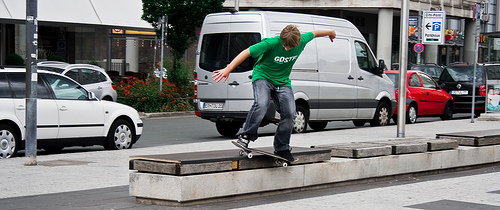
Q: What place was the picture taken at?
A: It was taken at the sidewalk.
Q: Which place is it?
A: It is a sidewalk.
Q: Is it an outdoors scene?
A: Yes, it is outdoors.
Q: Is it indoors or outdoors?
A: It is outdoors.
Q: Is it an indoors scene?
A: No, it is outdoors.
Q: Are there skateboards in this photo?
A: Yes, there is a skateboard.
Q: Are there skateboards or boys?
A: Yes, there is a skateboard.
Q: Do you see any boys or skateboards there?
A: Yes, there is a skateboard.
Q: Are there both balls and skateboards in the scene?
A: No, there is a skateboard but no balls.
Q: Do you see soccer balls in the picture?
A: No, there are no soccer balls.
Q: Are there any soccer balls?
A: No, there are no soccer balls.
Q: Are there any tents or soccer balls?
A: No, there are no soccer balls or tents.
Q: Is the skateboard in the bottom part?
A: Yes, the skateboard is in the bottom of the image.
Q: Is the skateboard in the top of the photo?
A: No, the skateboard is in the bottom of the image.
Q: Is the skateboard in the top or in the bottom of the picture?
A: The skateboard is in the bottom of the image.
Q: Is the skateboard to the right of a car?
A: Yes, the skateboard is to the right of a car.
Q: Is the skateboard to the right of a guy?
A: No, the skateboard is to the right of a car.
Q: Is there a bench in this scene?
A: Yes, there is a bench.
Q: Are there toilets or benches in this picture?
A: Yes, there is a bench.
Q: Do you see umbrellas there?
A: No, there are no umbrellas.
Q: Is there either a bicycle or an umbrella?
A: No, there are no umbrellas or bicycles.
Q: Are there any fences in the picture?
A: No, there are no fences.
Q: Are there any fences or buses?
A: No, there are no fences or buses.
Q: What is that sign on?
A: The sign is on the pole.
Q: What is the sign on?
A: The sign is on the pole.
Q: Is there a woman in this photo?
A: No, there are no women.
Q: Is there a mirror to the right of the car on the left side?
A: No, there is a boy to the right of the car.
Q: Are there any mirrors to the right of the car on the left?
A: No, there is a boy to the right of the car.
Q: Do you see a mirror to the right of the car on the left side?
A: No, there is a boy to the right of the car.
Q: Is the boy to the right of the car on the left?
A: Yes, the boy is to the right of the car.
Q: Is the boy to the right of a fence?
A: No, the boy is to the right of the car.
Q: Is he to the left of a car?
A: No, the boy is to the right of a car.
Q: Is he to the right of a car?
A: No, the boy is to the left of a car.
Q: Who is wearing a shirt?
A: The boy is wearing a shirt.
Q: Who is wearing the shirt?
A: The boy is wearing a shirt.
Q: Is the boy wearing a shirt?
A: Yes, the boy is wearing a shirt.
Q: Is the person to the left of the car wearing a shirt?
A: Yes, the boy is wearing a shirt.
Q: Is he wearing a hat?
A: No, the boy is wearing a shirt.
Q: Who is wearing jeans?
A: The boy is wearing jeans.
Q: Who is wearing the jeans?
A: The boy is wearing jeans.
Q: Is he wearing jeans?
A: Yes, the boy is wearing jeans.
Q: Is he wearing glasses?
A: No, the boy is wearing jeans.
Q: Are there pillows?
A: No, there are no pillows.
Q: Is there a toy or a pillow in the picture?
A: No, there are no pillows or toys.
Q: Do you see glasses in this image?
A: No, there are no glasses.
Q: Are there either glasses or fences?
A: No, there are no glasses or fences.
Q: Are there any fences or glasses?
A: No, there are no glasses or fences.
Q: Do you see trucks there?
A: No, there are no trucks.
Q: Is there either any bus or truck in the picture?
A: No, there are no trucks or buses.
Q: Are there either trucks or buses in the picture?
A: No, there are no trucks or buses.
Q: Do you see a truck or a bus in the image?
A: No, there are no trucks or buses.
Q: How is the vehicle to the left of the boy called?
A: The vehicle is a car.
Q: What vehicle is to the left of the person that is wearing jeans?
A: The vehicle is a car.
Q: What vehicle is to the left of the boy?
A: The vehicle is a car.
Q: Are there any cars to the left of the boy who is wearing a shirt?
A: Yes, there is a car to the left of the boy.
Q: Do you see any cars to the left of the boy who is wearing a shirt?
A: Yes, there is a car to the left of the boy.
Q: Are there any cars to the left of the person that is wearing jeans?
A: Yes, there is a car to the left of the boy.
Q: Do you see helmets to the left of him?
A: No, there is a car to the left of the boy.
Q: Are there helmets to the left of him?
A: No, there is a car to the left of the boy.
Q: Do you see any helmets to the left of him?
A: No, there is a car to the left of the boy.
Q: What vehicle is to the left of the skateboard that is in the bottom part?
A: The vehicle is a car.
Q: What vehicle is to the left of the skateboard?
A: The vehicle is a car.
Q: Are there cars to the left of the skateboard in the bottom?
A: Yes, there is a car to the left of the skateboard.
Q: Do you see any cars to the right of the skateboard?
A: No, the car is to the left of the skateboard.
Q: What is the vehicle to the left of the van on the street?
A: The vehicle is a car.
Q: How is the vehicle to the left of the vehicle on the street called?
A: The vehicle is a car.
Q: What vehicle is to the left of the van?
A: The vehicle is a car.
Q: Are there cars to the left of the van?
A: Yes, there is a car to the left of the van.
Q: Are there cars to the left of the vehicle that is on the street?
A: Yes, there is a car to the left of the van.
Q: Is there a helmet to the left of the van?
A: No, there is a car to the left of the van.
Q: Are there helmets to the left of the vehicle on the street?
A: No, there is a car to the left of the van.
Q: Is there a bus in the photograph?
A: No, there are no buses.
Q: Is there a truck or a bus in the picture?
A: No, there are no buses or trucks.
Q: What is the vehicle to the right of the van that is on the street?
A: The vehicle is a car.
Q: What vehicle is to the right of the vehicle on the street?
A: The vehicle is a car.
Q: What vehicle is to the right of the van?
A: The vehicle is a car.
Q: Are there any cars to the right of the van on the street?
A: Yes, there is a car to the right of the van.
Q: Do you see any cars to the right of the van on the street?
A: Yes, there is a car to the right of the van.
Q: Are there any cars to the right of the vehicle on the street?
A: Yes, there is a car to the right of the van.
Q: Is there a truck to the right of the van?
A: No, there is a car to the right of the van.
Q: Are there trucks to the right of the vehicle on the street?
A: No, there is a car to the right of the van.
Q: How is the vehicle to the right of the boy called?
A: The vehicle is a car.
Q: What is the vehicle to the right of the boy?
A: The vehicle is a car.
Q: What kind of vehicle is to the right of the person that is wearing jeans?
A: The vehicle is a car.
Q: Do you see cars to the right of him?
A: Yes, there is a car to the right of the boy.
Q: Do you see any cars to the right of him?
A: Yes, there is a car to the right of the boy.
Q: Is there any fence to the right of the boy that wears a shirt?
A: No, there is a car to the right of the boy.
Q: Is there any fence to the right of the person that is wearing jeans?
A: No, there is a car to the right of the boy.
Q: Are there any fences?
A: No, there are no fences.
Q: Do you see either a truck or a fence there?
A: No, there are no fences or trucks.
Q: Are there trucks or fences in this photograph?
A: No, there are no fences or trucks.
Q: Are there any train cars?
A: No, there are no train cars.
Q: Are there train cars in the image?
A: No, there are no train cars.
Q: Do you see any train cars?
A: No, there are no train cars.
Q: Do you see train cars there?
A: No, there are no train cars.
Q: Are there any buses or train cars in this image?
A: No, there are no train cars or buses.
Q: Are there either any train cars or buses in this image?
A: No, there are no train cars or buses.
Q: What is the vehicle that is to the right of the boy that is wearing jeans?
A: The vehicle is a car.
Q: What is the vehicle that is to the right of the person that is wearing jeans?
A: The vehicle is a car.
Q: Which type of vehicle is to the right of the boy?
A: The vehicle is a car.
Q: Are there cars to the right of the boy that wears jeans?
A: Yes, there is a car to the right of the boy.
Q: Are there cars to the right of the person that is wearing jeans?
A: Yes, there is a car to the right of the boy.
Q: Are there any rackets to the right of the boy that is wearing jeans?
A: No, there is a car to the right of the boy.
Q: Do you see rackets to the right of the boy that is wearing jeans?
A: No, there is a car to the right of the boy.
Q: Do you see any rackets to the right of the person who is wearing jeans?
A: No, there is a car to the right of the boy.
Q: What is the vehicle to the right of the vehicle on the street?
A: The vehicle is a car.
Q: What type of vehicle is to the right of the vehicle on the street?
A: The vehicle is a car.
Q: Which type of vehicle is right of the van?
A: The vehicle is a car.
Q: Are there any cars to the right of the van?
A: Yes, there is a car to the right of the van.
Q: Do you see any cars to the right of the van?
A: Yes, there is a car to the right of the van.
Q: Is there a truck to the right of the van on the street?
A: No, there is a car to the right of the van.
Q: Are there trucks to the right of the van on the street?
A: No, there is a car to the right of the van.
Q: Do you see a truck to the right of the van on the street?
A: No, there is a car to the right of the van.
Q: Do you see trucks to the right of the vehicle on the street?
A: No, there is a car to the right of the van.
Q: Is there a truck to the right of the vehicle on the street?
A: No, there is a car to the right of the van.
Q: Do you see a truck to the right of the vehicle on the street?
A: No, there is a car to the right of the van.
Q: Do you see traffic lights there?
A: No, there are no traffic lights.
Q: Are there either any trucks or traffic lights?
A: No, there are no traffic lights or trucks.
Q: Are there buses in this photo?
A: No, there are no buses.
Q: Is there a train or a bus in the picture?
A: No, there are no buses or trains.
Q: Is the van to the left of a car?
A: Yes, the van is to the left of a car.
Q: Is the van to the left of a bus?
A: No, the van is to the left of a car.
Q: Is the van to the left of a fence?
A: No, the van is to the left of a car.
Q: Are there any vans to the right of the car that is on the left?
A: Yes, there is a van to the right of the car.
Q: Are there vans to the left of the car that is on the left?
A: No, the van is to the right of the car.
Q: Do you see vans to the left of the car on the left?
A: No, the van is to the right of the car.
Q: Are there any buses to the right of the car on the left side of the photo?
A: No, there is a van to the right of the car.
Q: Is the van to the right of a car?
A: Yes, the van is to the right of a car.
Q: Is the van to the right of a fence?
A: No, the van is to the right of a car.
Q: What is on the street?
A: The van is on the street.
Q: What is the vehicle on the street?
A: The vehicle is a van.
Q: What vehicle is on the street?
A: The vehicle is a van.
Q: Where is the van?
A: The van is on the street.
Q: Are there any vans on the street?
A: Yes, there is a van on the street.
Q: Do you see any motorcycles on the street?
A: No, there is a van on the street.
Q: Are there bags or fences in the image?
A: No, there are no fences or bags.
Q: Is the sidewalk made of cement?
A: Yes, the sidewalk is made of cement.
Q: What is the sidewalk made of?
A: The sidewalk is made of concrete.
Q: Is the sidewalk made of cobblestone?
A: No, the sidewalk is made of concrete.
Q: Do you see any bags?
A: No, there are no bags.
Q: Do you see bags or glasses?
A: No, there are no bags or glasses.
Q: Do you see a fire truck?
A: No, there are no fire trucks.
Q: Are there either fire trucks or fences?
A: No, there are no fire trucks or fences.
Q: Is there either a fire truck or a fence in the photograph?
A: No, there are no fire trucks or fences.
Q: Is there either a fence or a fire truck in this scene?
A: No, there are no fire trucks or fences.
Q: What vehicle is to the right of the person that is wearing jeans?
A: The vehicle is a car.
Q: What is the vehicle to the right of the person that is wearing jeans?
A: The vehicle is a car.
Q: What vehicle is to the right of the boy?
A: The vehicle is a car.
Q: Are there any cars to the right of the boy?
A: Yes, there is a car to the right of the boy.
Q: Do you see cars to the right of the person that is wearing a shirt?
A: Yes, there is a car to the right of the boy.